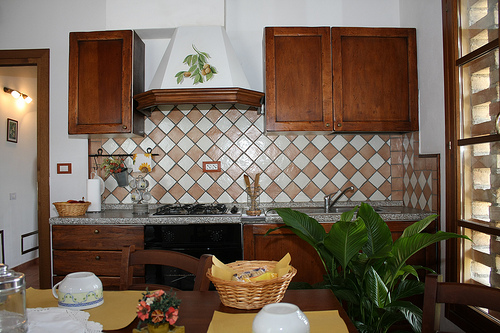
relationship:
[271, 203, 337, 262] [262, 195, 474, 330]
leaf of green plant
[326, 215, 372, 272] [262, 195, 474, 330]
leaf of green plant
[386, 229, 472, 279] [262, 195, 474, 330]
leaf of green plant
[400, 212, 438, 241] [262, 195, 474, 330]
leaf of green plant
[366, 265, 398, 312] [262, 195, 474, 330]
leaf of green plant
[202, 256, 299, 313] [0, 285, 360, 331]
wicker basket on table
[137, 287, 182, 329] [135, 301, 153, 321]
bouquet of flower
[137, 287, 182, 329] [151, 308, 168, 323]
bouquet of flower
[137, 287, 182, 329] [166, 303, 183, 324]
bouquet of flower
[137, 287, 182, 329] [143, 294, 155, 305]
bouquet of flower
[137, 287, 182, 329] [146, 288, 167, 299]
bouquet of flower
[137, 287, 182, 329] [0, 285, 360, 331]
bouquet on table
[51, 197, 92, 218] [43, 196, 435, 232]
basket on counter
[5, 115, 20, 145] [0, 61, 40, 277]
picture on wall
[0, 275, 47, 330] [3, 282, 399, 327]
jar on table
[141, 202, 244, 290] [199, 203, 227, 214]
oven with burners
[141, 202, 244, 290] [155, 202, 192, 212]
oven with burners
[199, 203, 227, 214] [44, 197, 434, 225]
burners on counter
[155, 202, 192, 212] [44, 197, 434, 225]
burners on counter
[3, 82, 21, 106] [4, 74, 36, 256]
fixture on wall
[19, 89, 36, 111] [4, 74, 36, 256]
fixture on wall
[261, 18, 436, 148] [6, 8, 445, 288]
cabinets on wall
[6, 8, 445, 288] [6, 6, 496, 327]
wall of kitchen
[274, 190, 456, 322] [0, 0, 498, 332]
plant in room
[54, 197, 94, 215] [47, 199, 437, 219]
basket on counter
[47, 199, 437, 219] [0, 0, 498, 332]
counter in room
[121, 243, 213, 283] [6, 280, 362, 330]
chair at table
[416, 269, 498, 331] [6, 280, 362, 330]
chair at table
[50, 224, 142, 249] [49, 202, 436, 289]
drawer at counter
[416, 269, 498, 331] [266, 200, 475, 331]
chair by plant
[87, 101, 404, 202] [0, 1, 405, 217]
tile on wall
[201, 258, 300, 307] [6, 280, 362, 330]
basket on table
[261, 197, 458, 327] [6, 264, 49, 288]
peace lily on floor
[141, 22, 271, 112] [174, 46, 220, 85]
hood with plant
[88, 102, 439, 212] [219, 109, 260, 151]
backsplash with diamond pattern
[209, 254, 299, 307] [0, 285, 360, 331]
basket on table